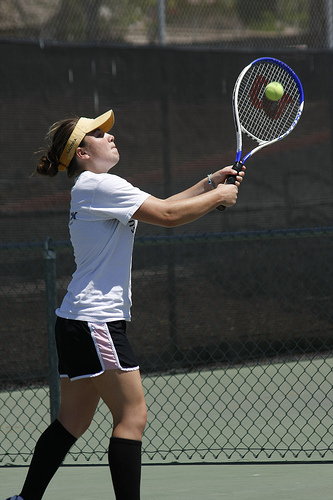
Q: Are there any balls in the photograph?
A: Yes, there is a ball.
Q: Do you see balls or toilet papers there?
A: Yes, there is a ball.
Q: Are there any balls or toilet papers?
A: Yes, there is a ball.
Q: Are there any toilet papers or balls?
A: Yes, there is a ball.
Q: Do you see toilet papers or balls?
A: Yes, there is a ball.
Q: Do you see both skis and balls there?
A: No, there is a ball but no skis.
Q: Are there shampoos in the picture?
A: No, there are no shampoos.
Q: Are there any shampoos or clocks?
A: No, there are no shampoos or clocks.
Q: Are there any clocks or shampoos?
A: No, there are no shampoos or clocks.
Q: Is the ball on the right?
A: Yes, the ball is on the right of the image.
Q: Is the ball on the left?
A: No, the ball is on the right of the image.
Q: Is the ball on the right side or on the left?
A: The ball is on the right of the image.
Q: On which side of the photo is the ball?
A: The ball is on the right of the image.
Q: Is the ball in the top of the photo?
A: Yes, the ball is in the top of the image.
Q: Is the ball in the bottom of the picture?
A: No, the ball is in the top of the image.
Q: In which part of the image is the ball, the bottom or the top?
A: The ball is in the top of the image.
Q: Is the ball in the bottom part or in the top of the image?
A: The ball is in the top of the image.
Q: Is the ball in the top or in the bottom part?
A: The ball is in the top of the image.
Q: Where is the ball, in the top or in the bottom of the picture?
A: The ball is in the top of the image.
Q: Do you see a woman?
A: Yes, there is a woman.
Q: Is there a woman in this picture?
A: Yes, there is a woman.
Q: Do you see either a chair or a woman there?
A: Yes, there is a woman.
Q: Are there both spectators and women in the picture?
A: No, there is a woman but no spectators.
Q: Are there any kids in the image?
A: No, there are no kids.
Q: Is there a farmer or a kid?
A: No, there are no children or farmers.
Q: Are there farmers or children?
A: No, there are no children or farmers.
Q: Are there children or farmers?
A: No, there are no children or farmers.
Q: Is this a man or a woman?
A: This is a woman.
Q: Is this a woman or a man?
A: This is a woman.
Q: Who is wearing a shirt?
A: The woman is wearing a shirt.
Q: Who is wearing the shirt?
A: The woman is wearing a shirt.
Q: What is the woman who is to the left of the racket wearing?
A: The woman is wearing a shirt.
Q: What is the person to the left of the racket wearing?
A: The woman is wearing a shirt.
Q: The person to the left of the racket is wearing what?
A: The woman is wearing a shirt.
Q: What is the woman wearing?
A: The woman is wearing a shirt.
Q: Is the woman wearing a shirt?
A: Yes, the woman is wearing a shirt.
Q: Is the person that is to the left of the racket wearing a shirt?
A: Yes, the woman is wearing a shirt.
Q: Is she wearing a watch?
A: No, the woman is wearing a shirt.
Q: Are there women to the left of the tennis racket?
A: Yes, there is a woman to the left of the tennis racket.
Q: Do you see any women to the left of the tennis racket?
A: Yes, there is a woman to the left of the tennis racket.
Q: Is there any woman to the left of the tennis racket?
A: Yes, there is a woman to the left of the tennis racket.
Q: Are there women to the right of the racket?
A: No, the woman is to the left of the racket.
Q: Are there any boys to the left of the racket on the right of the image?
A: No, there is a woman to the left of the tennis racket.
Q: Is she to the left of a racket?
A: Yes, the woman is to the left of a racket.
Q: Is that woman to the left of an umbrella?
A: No, the woman is to the left of a racket.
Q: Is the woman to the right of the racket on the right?
A: No, the woman is to the left of the racket.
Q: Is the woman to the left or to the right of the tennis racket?
A: The woman is to the left of the tennis racket.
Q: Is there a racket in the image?
A: Yes, there is a racket.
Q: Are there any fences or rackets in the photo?
A: Yes, there is a racket.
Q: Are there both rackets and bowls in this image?
A: No, there is a racket but no bowls.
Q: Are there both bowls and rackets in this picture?
A: No, there is a racket but no bowls.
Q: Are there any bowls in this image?
A: No, there are no bowls.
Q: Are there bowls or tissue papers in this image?
A: No, there are no bowls or tissue papers.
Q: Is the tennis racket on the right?
A: Yes, the tennis racket is on the right of the image.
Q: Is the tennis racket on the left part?
A: No, the tennis racket is on the right of the image.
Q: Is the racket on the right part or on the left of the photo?
A: The racket is on the right of the image.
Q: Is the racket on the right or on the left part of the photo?
A: The racket is on the right of the image.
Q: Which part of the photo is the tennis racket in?
A: The tennis racket is on the right of the image.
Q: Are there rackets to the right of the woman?
A: Yes, there is a racket to the right of the woman.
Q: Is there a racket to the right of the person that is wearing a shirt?
A: Yes, there is a racket to the right of the woman.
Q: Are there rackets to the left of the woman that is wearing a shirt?
A: No, the racket is to the right of the woman.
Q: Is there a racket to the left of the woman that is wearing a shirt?
A: No, the racket is to the right of the woman.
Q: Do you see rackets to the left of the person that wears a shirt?
A: No, the racket is to the right of the woman.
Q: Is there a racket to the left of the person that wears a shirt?
A: No, the racket is to the right of the woman.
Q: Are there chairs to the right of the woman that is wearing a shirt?
A: No, there is a racket to the right of the woman.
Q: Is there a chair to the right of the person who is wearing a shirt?
A: No, there is a racket to the right of the woman.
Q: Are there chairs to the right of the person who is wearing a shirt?
A: No, there is a racket to the right of the woman.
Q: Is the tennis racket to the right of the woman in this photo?
A: Yes, the tennis racket is to the right of the woman.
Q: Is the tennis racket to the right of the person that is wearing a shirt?
A: Yes, the tennis racket is to the right of the woman.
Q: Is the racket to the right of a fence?
A: No, the racket is to the right of the woman.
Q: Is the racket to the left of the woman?
A: No, the racket is to the right of the woman.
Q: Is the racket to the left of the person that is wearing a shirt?
A: No, the racket is to the right of the woman.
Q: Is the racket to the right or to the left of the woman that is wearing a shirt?
A: The racket is to the right of the woman.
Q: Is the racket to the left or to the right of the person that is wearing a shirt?
A: The racket is to the right of the woman.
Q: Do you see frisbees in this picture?
A: No, there are no frisbees.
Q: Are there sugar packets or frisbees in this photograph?
A: No, there are no frisbees or sugar packets.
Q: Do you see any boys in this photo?
A: No, there are no boys.